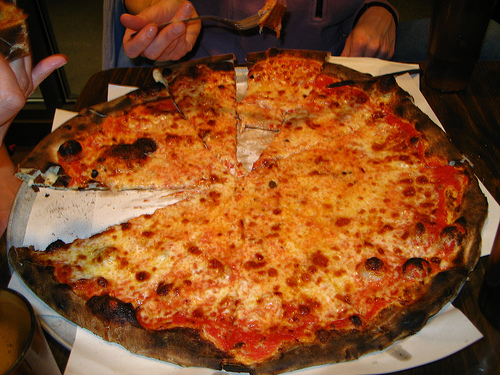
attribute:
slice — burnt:
[10, 112, 207, 190]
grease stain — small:
[40, 169, 150, 250]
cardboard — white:
[12, 55, 499, 372]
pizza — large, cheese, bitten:
[9, 49, 487, 374]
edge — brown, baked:
[98, 328, 206, 365]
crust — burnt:
[165, 56, 241, 75]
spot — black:
[87, 285, 143, 332]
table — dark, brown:
[30, 53, 473, 373]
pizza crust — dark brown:
[8, 266, 471, 373]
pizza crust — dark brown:
[412, 57, 487, 304]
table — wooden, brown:
[69, 66, 160, 109]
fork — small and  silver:
[127, 2, 285, 48]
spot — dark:
[134, 138, 156, 152]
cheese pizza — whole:
[5, 47, 488, 373]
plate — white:
[29, 194, 61, 234]